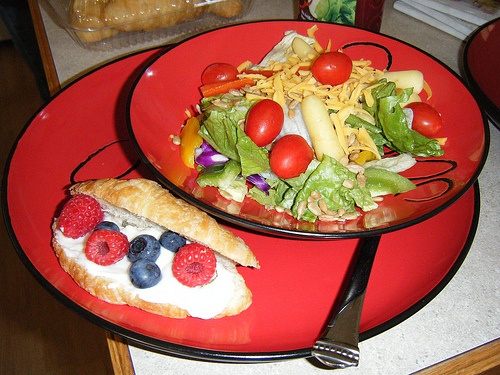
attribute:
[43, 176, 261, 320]
treat — raspberry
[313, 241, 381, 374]
fork — silver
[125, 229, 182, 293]
blueberry — four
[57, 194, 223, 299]
raspberry — red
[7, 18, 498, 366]
plate — red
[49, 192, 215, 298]
cherry — small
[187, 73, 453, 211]
lettuce — green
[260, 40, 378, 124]
cheese — shredded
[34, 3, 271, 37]
container — plastic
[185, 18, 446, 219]
vegetable — two plate, plate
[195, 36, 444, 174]
cranberry — fresh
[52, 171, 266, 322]
bread — clear box, coissants, open, small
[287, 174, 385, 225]
seeds — bunch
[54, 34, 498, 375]
counter — off white